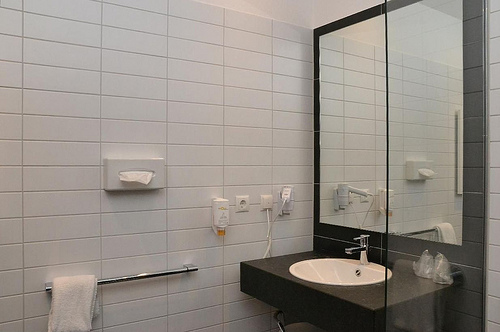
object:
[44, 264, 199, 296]
rack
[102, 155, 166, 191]
box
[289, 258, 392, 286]
sink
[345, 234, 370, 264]
faucet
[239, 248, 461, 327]
counter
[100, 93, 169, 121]
tile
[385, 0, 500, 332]
wall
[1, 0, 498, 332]
bathroom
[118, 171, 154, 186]
napkin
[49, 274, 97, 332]
towel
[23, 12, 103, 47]
tile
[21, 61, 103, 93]
tile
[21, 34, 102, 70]
tile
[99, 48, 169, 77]
tile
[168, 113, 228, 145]
tile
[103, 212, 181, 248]
tile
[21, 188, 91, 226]
tile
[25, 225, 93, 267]
tile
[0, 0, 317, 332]
wall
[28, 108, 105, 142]
tile